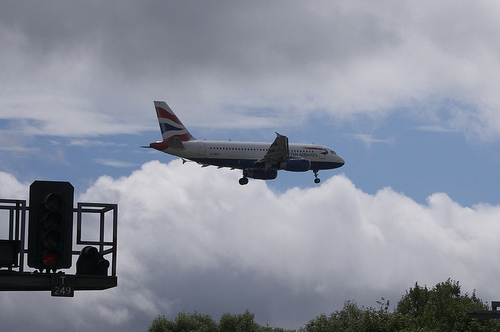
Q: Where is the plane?
A: In sky.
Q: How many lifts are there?
A: 1.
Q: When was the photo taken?
A: Daytime.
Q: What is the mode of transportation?
A: Airplane.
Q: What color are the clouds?
A: Grey and white.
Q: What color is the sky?
A: Blue.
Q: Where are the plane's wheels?
A: Out underneath plane.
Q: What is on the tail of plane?
A: Blue and red stripes.